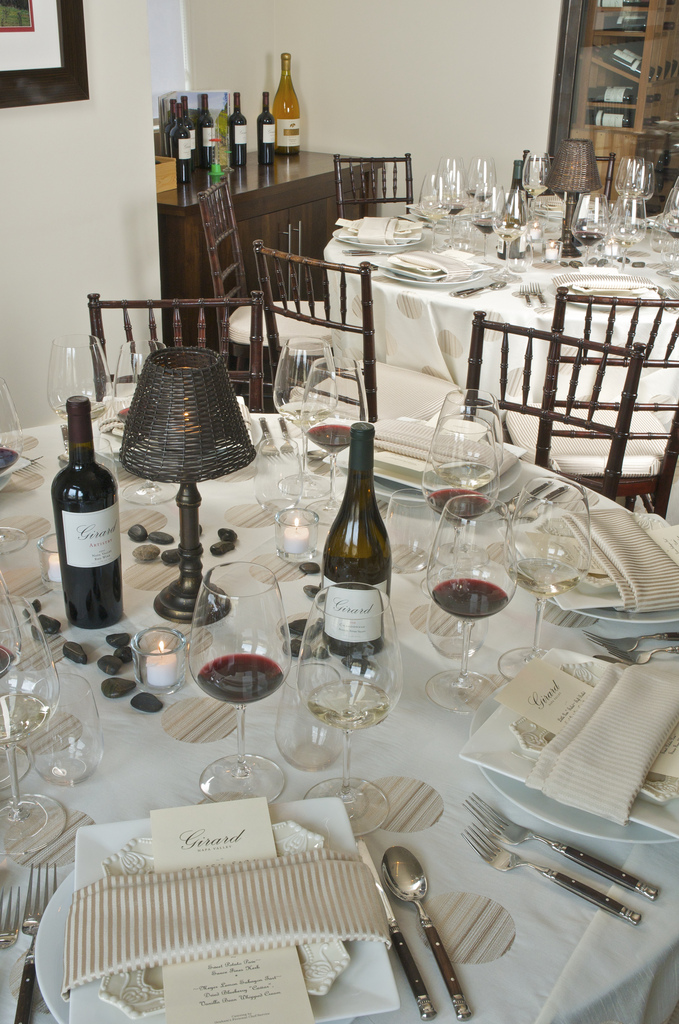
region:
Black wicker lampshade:
[108, 343, 262, 627]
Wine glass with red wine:
[184, 558, 298, 813]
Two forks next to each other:
[457, 787, 664, 929]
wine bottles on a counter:
[151, 47, 381, 386]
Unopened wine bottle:
[48, 392, 127, 634]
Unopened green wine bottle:
[317, 420, 397, 664]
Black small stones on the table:
[22, 519, 339, 715]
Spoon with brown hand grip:
[379, 841, 475, 1020]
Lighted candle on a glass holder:
[125, 624, 190, 697]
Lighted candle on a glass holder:
[272, 503, 323, 565]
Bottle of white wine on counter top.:
[268, 43, 304, 153]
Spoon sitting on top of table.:
[382, 846, 468, 1017]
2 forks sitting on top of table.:
[460, 787, 652, 952]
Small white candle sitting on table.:
[134, 619, 194, 693]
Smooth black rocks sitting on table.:
[60, 626, 159, 721]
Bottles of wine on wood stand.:
[158, 87, 287, 190]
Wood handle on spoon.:
[426, 920, 464, 1006]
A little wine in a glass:
[178, 549, 305, 811]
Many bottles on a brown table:
[146, 36, 390, 348]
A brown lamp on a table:
[103, 327, 263, 633]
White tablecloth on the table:
[307, 195, 671, 433]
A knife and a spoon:
[342, 824, 477, 1018]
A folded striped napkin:
[53, 840, 398, 997]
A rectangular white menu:
[483, 647, 674, 783]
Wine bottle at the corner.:
[158, 55, 311, 184]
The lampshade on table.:
[122, 345, 254, 621]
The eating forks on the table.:
[462, 794, 660, 925]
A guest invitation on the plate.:
[34, 800, 398, 1022]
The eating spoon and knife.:
[352, 839, 471, 1021]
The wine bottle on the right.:
[322, 422, 393, 654]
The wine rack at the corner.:
[554, 1, 678, 195]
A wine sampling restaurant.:
[0, 0, 678, 1023]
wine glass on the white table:
[184, 553, 291, 813]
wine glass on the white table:
[300, 578, 397, 835]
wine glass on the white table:
[424, 489, 516, 716]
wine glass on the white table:
[496, 472, 583, 689]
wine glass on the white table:
[419, 406, 498, 583]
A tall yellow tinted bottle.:
[271, 53, 302, 157]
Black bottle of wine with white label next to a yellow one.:
[255, 92, 275, 164]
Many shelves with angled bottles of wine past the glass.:
[557, 1, 678, 208]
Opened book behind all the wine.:
[157, 89, 231, 157]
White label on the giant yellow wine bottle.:
[274, 118, 301, 147]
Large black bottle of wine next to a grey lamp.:
[51, 396, 127, 628]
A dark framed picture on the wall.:
[1, 2, 90, 111]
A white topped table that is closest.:
[1, 400, 678, 1020]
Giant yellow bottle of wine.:
[269, 53, 301, 154]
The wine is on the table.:
[37, 392, 132, 636]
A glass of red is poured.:
[186, 571, 298, 796]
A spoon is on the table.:
[376, 843, 480, 1009]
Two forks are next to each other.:
[459, 784, 665, 933]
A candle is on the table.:
[116, 343, 257, 488]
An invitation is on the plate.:
[85, 823, 366, 1016]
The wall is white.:
[340, 23, 481, 123]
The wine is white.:
[504, 471, 591, 670]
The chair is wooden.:
[242, 242, 388, 406]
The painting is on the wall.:
[0, 0, 107, 113]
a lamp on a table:
[120, 349, 245, 624]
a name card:
[151, 799, 315, 1022]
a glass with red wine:
[189, 561, 289, 800]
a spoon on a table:
[385, 848, 469, 1016]